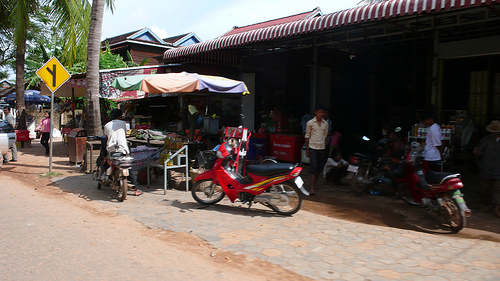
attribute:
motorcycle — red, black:
[188, 144, 312, 224]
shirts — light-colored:
[305, 122, 446, 164]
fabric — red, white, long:
[156, 0, 499, 62]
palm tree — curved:
[78, 1, 108, 138]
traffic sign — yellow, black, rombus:
[28, 53, 79, 96]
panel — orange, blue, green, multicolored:
[101, 68, 254, 111]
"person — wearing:
[34, 109, 57, 159]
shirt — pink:
[34, 117, 54, 133]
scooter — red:
[384, 151, 481, 242]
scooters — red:
[186, 137, 475, 240]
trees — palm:
[0, 0, 113, 136]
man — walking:
[301, 103, 332, 197]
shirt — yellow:
[303, 118, 331, 152]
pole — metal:
[45, 92, 58, 181]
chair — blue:
[144, 145, 191, 194]